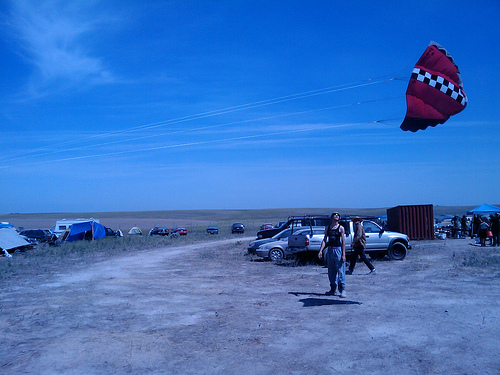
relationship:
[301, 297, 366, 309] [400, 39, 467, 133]
shadow of parachute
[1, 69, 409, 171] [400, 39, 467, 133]
strings on parachute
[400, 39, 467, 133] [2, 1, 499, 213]
parachute in sky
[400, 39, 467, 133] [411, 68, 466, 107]
parachute has checkered pattern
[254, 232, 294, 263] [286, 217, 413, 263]
car parked next to truck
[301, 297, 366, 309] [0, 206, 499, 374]
shadow on ground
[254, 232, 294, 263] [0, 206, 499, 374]
car parked on ground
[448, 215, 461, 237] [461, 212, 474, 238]
person next to person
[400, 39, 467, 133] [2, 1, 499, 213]
parachute flying in sky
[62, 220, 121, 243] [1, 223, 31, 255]
tent near tent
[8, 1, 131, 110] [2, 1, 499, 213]
cloud in sky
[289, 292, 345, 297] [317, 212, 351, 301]
shadow of woman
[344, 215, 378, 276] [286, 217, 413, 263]
person walking next to truck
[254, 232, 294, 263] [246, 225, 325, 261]
car parked next to car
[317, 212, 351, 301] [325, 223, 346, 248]
woman wearing tank top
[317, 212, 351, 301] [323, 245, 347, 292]
woman wearing blue pants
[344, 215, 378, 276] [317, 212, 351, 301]
person behind woman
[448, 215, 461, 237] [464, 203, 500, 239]
person near gazebo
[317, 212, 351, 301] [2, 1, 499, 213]
woman looking at sky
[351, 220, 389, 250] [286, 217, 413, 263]
door of truck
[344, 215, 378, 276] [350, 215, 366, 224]
person wearing hat